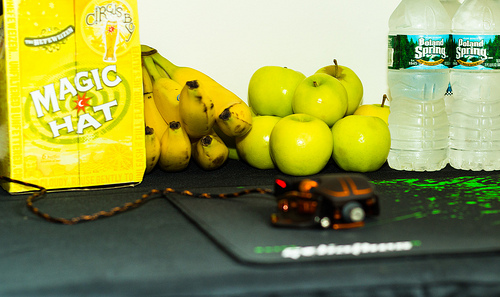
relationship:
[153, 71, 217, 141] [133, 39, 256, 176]
banana in bunch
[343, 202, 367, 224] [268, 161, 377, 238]
button on toy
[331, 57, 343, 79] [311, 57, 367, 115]
stem on apple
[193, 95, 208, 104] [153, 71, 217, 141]
spot on banana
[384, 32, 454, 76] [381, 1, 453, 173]
label on bottle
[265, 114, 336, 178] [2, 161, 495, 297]
apple on table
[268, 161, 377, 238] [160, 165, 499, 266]
toy on pad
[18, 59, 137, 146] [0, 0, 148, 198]
logo on carton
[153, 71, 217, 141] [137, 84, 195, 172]
banana on banana